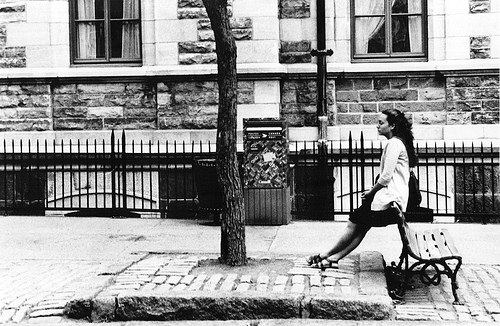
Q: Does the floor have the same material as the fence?
A: No, the floor is made of cement and the fence is made of metal.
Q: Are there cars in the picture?
A: No, there are no cars.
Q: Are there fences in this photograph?
A: Yes, there is a fence.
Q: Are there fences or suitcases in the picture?
A: Yes, there is a fence.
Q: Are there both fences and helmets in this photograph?
A: No, there is a fence but no helmets.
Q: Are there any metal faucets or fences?
A: Yes, there is a metal fence.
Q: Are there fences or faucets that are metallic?
A: Yes, the fence is metallic.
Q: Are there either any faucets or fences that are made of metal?
A: Yes, the fence is made of metal.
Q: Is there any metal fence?
A: Yes, there is a fence that is made of metal.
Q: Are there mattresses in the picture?
A: No, there are no mattresses.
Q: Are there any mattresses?
A: No, there are no mattresses.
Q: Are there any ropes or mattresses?
A: No, there are no mattresses or ropes.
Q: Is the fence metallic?
A: Yes, the fence is metallic.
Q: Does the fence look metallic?
A: Yes, the fence is metallic.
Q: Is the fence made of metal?
A: Yes, the fence is made of metal.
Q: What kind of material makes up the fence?
A: The fence is made of metal.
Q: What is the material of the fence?
A: The fence is made of metal.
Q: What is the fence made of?
A: The fence is made of metal.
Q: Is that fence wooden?
A: No, the fence is metallic.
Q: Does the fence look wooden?
A: No, the fence is metallic.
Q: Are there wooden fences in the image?
A: No, there is a fence but it is metallic.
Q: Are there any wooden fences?
A: No, there is a fence but it is metallic.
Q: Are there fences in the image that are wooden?
A: No, there is a fence but it is metallic.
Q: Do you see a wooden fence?
A: No, there is a fence but it is metallic.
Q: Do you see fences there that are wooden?
A: No, there is a fence but it is metallic.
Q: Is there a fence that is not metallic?
A: No, there is a fence but it is metallic.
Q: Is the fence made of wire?
A: No, the fence is made of metal.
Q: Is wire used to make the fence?
A: No, the fence is made of metal.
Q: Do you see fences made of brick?
A: No, there is a fence but it is made of metal.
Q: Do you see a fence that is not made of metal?
A: No, there is a fence but it is made of metal.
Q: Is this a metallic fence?
A: Yes, this is a metallic fence.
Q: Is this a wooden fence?
A: No, this is a metallic fence.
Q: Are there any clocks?
A: No, there are no clocks.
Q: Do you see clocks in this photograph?
A: No, there are no clocks.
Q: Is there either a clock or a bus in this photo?
A: No, there are no clocks or buses.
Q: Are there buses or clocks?
A: No, there are no clocks or buses.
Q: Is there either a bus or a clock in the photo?
A: No, there are no clocks or buses.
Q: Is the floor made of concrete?
A: Yes, the floor is made of concrete.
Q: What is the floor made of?
A: The floor is made of concrete.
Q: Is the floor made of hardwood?
A: No, the floor is made of cement.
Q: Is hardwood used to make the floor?
A: No, the floor is made of cement.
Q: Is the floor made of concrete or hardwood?
A: The floor is made of concrete.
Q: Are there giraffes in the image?
A: No, there are no giraffes.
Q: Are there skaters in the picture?
A: No, there are no skaters.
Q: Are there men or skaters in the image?
A: No, there are no skaters or men.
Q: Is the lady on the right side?
A: Yes, the lady is on the right of the image.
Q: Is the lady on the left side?
A: No, the lady is on the right of the image.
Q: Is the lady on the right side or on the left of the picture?
A: The lady is on the right of the image.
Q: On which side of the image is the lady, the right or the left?
A: The lady is on the right of the image.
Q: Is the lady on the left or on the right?
A: The lady is on the right of the image.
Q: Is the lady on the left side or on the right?
A: The lady is on the right of the image.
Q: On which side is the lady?
A: The lady is on the right of the image.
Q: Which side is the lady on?
A: The lady is on the right of the image.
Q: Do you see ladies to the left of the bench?
A: Yes, there is a lady to the left of the bench.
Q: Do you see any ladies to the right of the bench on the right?
A: No, the lady is to the left of the bench.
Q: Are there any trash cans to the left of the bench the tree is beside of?
A: No, there is a lady to the left of the bench.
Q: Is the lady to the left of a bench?
A: Yes, the lady is to the left of a bench.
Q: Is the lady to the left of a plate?
A: No, the lady is to the left of a bench.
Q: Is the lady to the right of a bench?
A: No, the lady is to the left of a bench.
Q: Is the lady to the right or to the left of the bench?
A: The lady is to the left of the bench.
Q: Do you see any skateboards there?
A: No, there are no skateboards.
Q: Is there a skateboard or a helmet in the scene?
A: No, there are no skateboards or helmets.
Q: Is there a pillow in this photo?
A: No, there are no pillows.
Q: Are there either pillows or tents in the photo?
A: No, there are no pillows or tents.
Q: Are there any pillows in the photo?
A: No, there are no pillows.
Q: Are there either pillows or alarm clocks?
A: No, there are no pillows or alarm clocks.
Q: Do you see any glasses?
A: No, there are no glasses.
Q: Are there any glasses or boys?
A: No, there are no glasses or boys.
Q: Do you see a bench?
A: Yes, there is a bench.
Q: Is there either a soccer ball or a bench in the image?
A: Yes, there is a bench.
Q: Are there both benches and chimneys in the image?
A: No, there is a bench but no chimneys.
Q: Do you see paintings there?
A: No, there are no paintings.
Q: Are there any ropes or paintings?
A: No, there are no paintings or ropes.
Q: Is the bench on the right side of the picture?
A: Yes, the bench is on the right of the image.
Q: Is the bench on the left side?
A: No, the bench is on the right of the image.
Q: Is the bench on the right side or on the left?
A: The bench is on the right of the image.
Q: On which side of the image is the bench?
A: The bench is on the right of the image.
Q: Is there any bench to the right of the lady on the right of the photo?
A: Yes, there is a bench to the right of the lady.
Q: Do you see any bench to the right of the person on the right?
A: Yes, there is a bench to the right of the lady.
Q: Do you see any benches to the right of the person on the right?
A: Yes, there is a bench to the right of the lady.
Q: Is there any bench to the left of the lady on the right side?
A: No, the bench is to the right of the lady.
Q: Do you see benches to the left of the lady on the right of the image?
A: No, the bench is to the right of the lady.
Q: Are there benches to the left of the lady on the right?
A: No, the bench is to the right of the lady.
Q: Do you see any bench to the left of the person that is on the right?
A: No, the bench is to the right of the lady.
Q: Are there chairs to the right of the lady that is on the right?
A: No, there is a bench to the right of the lady.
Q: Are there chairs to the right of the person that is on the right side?
A: No, there is a bench to the right of the lady.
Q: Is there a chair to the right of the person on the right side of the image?
A: No, there is a bench to the right of the lady.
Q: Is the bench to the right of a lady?
A: Yes, the bench is to the right of a lady.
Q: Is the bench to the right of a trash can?
A: No, the bench is to the right of a lady.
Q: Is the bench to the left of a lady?
A: No, the bench is to the right of a lady.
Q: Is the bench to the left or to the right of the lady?
A: The bench is to the right of the lady.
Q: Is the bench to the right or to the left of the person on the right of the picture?
A: The bench is to the right of the lady.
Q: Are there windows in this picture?
A: Yes, there is a window.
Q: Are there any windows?
A: Yes, there is a window.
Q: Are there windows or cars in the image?
A: Yes, there is a window.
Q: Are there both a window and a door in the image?
A: No, there is a window but no doors.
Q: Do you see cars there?
A: No, there are no cars.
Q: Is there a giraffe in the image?
A: No, there are no giraffes.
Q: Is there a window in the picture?
A: Yes, there is a window.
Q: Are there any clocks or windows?
A: Yes, there is a window.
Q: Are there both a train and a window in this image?
A: No, there is a window but no trains.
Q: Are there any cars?
A: No, there are no cars.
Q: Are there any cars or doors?
A: No, there are no cars or doors.